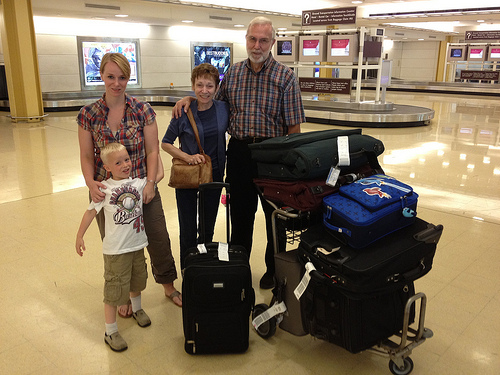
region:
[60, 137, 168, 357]
a young boy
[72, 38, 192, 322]
lady with short blond hair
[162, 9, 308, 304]
an older couple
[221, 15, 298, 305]
man in a plaid shirt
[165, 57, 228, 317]
woman in a blue outfit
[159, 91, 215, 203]
a brown leather handbag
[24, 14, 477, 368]
the airport baggage claim area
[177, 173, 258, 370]
a black suitcase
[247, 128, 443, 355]
a pile of luggage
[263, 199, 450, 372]
a luggage cart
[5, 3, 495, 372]
a group of people in what appears to be an airport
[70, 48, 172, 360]
woman standing behind a young boy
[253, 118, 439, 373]
several pieces of luggage loaded onto a cart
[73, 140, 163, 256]
baseball design on boy's shirt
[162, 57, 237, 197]
woman carrying a brown purse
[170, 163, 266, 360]
black piece of luggage with a handle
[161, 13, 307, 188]
man has his arm around the woman next to him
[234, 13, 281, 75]
man has facial hair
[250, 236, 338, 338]
long tag on luggage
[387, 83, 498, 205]
lights reflected on the floor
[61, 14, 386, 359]
a family of four at the airport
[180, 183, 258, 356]
black luggage on wheels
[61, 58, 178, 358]
little boy holding onto his mom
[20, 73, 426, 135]
gray baggage claim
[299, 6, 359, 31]
brown and white sign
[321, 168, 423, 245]
tiny blue luggage with birds on it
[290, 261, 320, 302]
white baggage claim tag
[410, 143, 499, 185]
reflection of the lights on the floor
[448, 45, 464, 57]
baggage claim monitor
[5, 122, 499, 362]
beige tiled floor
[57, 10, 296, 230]
the people are smiling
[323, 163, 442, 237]
the suitcase is blue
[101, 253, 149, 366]
the boy's shorts and shoes are brown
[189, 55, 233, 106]
the woman's hair is short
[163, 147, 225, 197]
the woman's purse is brown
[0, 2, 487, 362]
the people are in a airport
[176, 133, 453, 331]
the luggage has white tags on it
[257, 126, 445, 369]
the luggage is on a metal carrier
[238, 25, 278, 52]
the man is wearing glasses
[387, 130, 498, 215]
the light is reflecting on floor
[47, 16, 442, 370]
group of four people standing at the airport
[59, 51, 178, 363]
young boy holding onto his mother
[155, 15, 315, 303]
an older man with his arm around an older woman's shoulder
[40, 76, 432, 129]
shiny baggage claim carousel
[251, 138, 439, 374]
cart with luggage stacked on it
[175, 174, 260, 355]
black luggage with its handle pulled up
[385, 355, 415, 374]
tiny wheel on the luggage cart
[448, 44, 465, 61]
baggage claim monitor